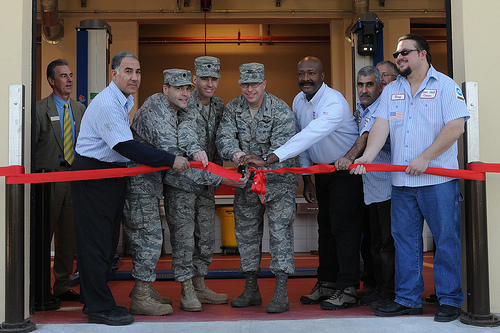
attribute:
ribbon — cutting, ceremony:
[1, 161, 498, 193]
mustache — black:
[295, 76, 318, 90]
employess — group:
[34, 29, 481, 319]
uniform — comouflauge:
[215, 89, 302, 274]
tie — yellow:
[55, 102, 78, 165]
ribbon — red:
[1, 157, 498, 185]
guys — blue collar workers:
[119, 34, 484, 189]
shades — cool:
[388, 45, 424, 59]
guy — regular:
[345, 1, 455, 289]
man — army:
[214, 62, 299, 312]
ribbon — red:
[0, 164, 500, 207]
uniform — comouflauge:
[221, 92, 297, 277]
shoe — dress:
[433, 303, 466, 325]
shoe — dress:
[370, 304, 415, 318]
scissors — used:
[238, 160, 258, 187]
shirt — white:
[276, 88, 363, 171]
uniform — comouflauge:
[120, 90, 220, 280]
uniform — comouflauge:
[169, 95, 230, 278]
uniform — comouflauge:
[116, 90, 217, 290]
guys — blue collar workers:
[338, 62, 401, 314]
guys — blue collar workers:
[69, 51, 194, 323]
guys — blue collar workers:
[369, 48, 399, 88]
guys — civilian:
[36, 59, 101, 313]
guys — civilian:
[63, 51, 186, 329]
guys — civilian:
[352, 31, 468, 320]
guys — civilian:
[336, 64, 388, 313]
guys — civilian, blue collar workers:
[260, 46, 363, 309]